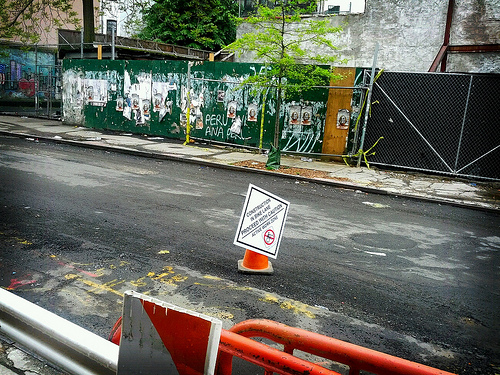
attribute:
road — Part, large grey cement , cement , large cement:
[0, 131, 499, 373]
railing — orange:
[104, 310, 460, 373]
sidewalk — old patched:
[1, 110, 498, 213]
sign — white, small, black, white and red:
[231, 182, 289, 261]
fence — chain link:
[16, 56, 496, 179]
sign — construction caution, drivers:
[121, 294, 187, 351]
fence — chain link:
[373, 68, 496, 182]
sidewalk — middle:
[356, 157, 452, 217]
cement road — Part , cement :
[0, 133, 499, 373]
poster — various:
[88, 77, 110, 108]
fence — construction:
[53, 52, 496, 182]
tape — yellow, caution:
[324, 73, 390, 169]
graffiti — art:
[0, 23, 62, 113]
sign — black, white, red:
[220, 183, 290, 262]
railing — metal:
[1, 286, 118, 371]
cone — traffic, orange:
[231, 249, 276, 276]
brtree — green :
[219, 0, 354, 147]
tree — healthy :
[222, 3, 348, 192]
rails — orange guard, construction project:
[215, 306, 396, 374]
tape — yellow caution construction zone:
[340, 68, 389, 170]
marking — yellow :
[12, 220, 187, 297]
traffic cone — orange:
[231, 178, 273, 281]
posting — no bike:
[262, 225, 274, 247]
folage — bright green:
[216, 14, 336, 176]